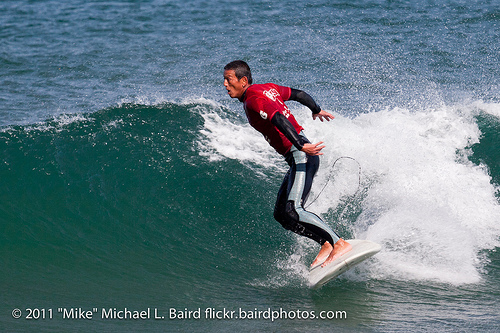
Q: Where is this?
A: This is at the ocean.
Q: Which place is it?
A: It is an ocean.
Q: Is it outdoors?
A: Yes, it is outdoors.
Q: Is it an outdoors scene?
A: Yes, it is outdoors.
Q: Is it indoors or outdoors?
A: It is outdoors.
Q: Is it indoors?
A: No, it is outdoors.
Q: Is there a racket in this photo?
A: No, there are no rackets.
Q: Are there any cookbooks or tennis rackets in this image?
A: No, there are no tennis rackets or cookbooks.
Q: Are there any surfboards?
A: Yes, there is a surfboard.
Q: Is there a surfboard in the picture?
A: Yes, there is a surfboard.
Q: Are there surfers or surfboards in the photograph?
A: Yes, there is a surfboard.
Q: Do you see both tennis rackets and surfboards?
A: No, there is a surfboard but no rackets.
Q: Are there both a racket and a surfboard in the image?
A: No, there is a surfboard but no rackets.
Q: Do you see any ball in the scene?
A: No, there are no balls.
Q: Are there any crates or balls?
A: No, there are no balls or crates.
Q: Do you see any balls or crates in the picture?
A: No, there are no balls or crates.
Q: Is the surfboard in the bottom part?
A: Yes, the surfboard is in the bottom of the image.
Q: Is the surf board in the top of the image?
A: No, the surf board is in the bottom of the image.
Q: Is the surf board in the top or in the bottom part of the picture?
A: The surf board is in the bottom of the image.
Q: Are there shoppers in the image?
A: No, there are no shoppers.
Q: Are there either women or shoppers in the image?
A: No, there are no shoppers or women.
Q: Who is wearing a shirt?
A: The man is wearing a shirt.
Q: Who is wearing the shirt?
A: The man is wearing a shirt.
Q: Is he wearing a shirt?
A: Yes, the man is wearing a shirt.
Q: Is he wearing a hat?
A: No, the man is wearing a shirt.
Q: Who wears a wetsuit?
A: The man wears a wetsuit.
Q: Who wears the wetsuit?
A: The man wears a wetsuit.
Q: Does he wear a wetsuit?
A: Yes, the man wears a wetsuit.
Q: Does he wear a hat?
A: No, the man wears a wetsuit.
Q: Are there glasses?
A: No, there are no glasses.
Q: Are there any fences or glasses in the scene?
A: No, there are no glasses or fences.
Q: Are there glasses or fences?
A: No, there are no glasses or fences.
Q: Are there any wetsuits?
A: Yes, there is a wetsuit.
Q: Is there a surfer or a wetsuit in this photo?
A: Yes, there is a wetsuit.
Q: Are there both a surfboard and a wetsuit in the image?
A: Yes, there are both a wetsuit and a surfboard.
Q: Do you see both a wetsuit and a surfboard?
A: Yes, there are both a wetsuit and a surfboard.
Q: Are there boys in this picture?
A: No, there are no boys.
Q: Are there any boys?
A: No, there are no boys.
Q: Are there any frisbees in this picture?
A: No, there are no frisbees.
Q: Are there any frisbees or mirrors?
A: No, there are no frisbees or mirrors.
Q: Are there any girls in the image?
A: No, there are no girls.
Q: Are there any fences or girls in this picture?
A: No, there are no girls or fences.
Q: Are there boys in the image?
A: No, there are no boys.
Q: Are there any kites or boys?
A: No, there are no boys or kites.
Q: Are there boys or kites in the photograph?
A: No, there are no boys or kites.